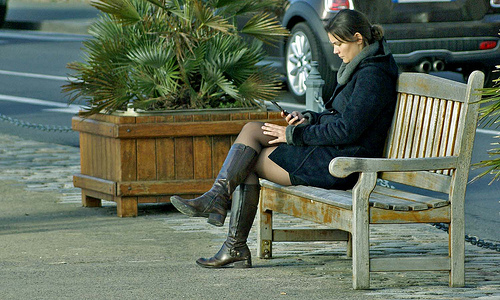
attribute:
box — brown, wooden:
[70, 106, 286, 216]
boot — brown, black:
[167, 140, 262, 229]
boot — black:
[194, 180, 261, 270]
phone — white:
[271, 95, 296, 123]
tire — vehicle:
[268, 10, 356, 112]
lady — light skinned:
[170, 7, 398, 268]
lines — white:
[5, 58, 499, 162]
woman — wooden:
[172, 10, 397, 265]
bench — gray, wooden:
[253, 62, 483, 292]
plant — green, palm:
[86, 15, 282, 122]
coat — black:
[270, 57, 399, 200]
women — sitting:
[187, 21, 409, 277]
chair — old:
[253, 69, 485, 281]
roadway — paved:
[4, 28, 101, 152]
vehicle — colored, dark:
[193, 0, 497, 106]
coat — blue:
[269, 51, 397, 190]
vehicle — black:
[207, 1, 497, 101]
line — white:
[2, 93, 99, 117]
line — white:
[2, 65, 499, 136]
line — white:
[0, 27, 100, 44]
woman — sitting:
[126, 66, 325, 224]